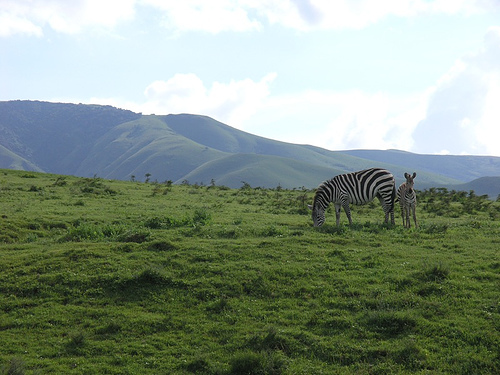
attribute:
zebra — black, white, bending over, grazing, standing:
[312, 168, 397, 228]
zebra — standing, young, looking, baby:
[398, 170, 420, 228]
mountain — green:
[4, 169, 486, 367]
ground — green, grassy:
[9, 169, 494, 371]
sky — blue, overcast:
[3, 4, 500, 156]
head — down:
[314, 200, 331, 226]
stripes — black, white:
[309, 168, 399, 229]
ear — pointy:
[413, 171, 418, 181]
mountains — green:
[1, 95, 496, 202]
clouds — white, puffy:
[4, 9, 496, 151]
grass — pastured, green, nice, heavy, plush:
[3, 169, 499, 371]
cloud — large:
[413, 65, 499, 168]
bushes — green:
[5, 171, 499, 367]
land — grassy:
[5, 169, 496, 374]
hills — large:
[5, 96, 499, 211]